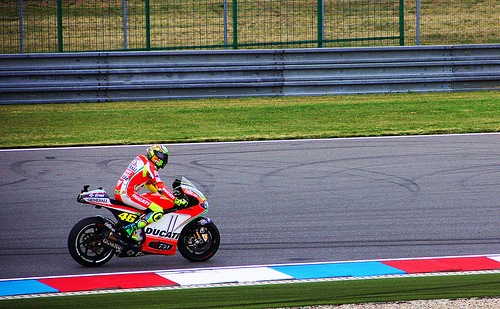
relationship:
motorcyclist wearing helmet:
[112, 142, 188, 243] [145, 140, 169, 166]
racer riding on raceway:
[112, 143, 189, 243] [1, 145, 499, 299]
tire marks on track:
[1, 140, 499, 260] [2, 133, 499, 277]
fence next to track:
[6, 5, 498, 43] [2, 133, 499, 277]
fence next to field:
[6, 5, 498, 43] [4, 3, 497, 53]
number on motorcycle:
[117, 210, 137, 223] [81, 145, 228, 259]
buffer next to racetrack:
[2, 251, 499, 298] [3, 131, 497, 280]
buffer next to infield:
[2, 251, 499, 298] [3, 274, 498, 306]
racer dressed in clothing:
[112, 143, 189, 243] [115, 153, 189, 240]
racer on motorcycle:
[112, 143, 189, 243] [81, 145, 228, 259]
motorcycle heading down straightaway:
[81, 145, 228, 259] [2, 130, 499, 277]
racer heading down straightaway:
[112, 143, 189, 243] [2, 130, 499, 277]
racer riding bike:
[112, 143, 189, 243] [67, 173, 220, 266]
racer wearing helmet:
[112, 143, 189, 243] [147, 143, 167, 168]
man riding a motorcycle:
[108, 140, 189, 245] [81, 145, 228, 259]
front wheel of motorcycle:
[172, 216, 222, 265] [64, 164, 225, 260]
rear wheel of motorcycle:
[62, 207, 122, 270] [72, 182, 228, 263]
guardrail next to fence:
[1, 47, 499, 92] [6, 5, 498, 43]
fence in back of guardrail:
[6, 5, 498, 43] [1, 47, 499, 92]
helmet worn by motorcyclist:
[144, 140, 174, 170] [110, 138, 177, 239]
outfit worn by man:
[115, 160, 167, 236] [108, 138, 182, 252]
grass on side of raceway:
[0, 88, 497, 152] [1, 145, 499, 299]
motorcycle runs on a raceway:
[81, 145, 228, 259] [1, 145, 499, 299]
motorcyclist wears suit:
[112, 142, 188, 243] [115, 151, 182, 247]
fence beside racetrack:
[6, 5, 498, 43] [3, 131, 497, 280]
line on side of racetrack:
[2, 248, 499, 298] [3, 131, 497, 280]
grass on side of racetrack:
[0, 88, 497, 152] [3, 131, 497, 280]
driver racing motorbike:
[113, 140, 191, 249] [65, 175, 224, 265]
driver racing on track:
[113, 140, 191, 249] [2, 133, 499, 277]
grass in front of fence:
[0, 88, 497, 152] [0, 3, 421, 53]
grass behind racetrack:
[0, 88, 497, 152] [3, 131, 497, 280]